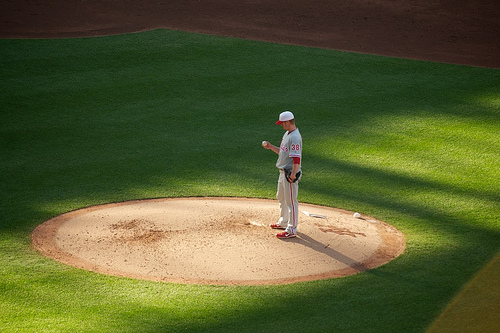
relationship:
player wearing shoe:
[265, 109, 301, 242] [277, 230, 293, 239]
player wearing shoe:
[265, 109, 301, 242] [272, 221, 281, 229]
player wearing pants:
[265, 109, 301, 242] [275, 172, 298, 229]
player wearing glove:
[265, 109, 301, 242] [284, 168, 302, 183]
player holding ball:
[265, 109, 301, 242] [260, 141, 270, 147]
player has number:
[265, 109, 301, 242] [294, 143, 302, 152]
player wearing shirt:
[265, 109, 301, 242] [276, 130, 301, 176]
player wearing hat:
[265, 109, 301, 242] [276, 111, 295, 127]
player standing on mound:
[265, 109, 301, 242] [30, 197, 408, 287]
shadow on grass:
[2, 2, 500, 332] [5, 25, 499, 331]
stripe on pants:
[289, 181, 299, 231] [275, 172, 298, 229]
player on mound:
[265, 109, 301, 242] [30, 197, 408, 287]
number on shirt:
[294, 143, 302, 152] [276, 130, 301, 176]